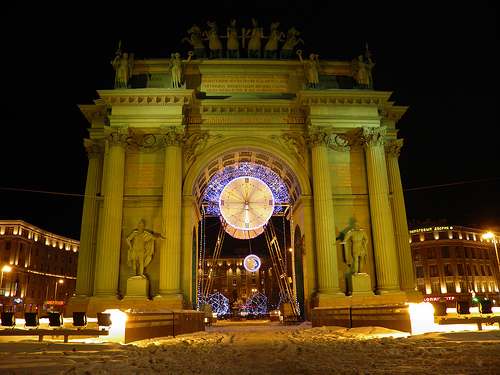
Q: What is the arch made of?
A: Stone.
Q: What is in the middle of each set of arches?
A: A statue.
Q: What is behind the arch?
A: A building.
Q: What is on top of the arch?
A: More statues.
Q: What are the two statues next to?
A: Columns.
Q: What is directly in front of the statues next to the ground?
A: Lights.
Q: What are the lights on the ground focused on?
A: The statues.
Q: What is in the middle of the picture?
A: A golden clock.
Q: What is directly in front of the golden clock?
A: Two short walls leading to the monument.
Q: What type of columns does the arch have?
A: Roman.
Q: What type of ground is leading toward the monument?
A: Sand.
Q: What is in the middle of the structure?
A: A clock.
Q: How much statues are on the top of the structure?
A: Ten.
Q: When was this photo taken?
A: At night.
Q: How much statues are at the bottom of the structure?
A: Two.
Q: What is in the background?
A: Buildings.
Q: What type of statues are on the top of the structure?
A: Horse statues.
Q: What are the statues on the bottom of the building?
A: Statues of people.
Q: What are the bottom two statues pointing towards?
A: The entrance.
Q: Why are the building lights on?
A: It's nighttime.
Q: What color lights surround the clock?
A: Blue.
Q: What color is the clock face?
A: Gold.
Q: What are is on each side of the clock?
A: Statues.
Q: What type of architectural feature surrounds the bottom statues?
A: Columns.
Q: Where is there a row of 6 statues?
A: On top of the structure.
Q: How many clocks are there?
A: 1.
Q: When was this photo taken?
A: Night.